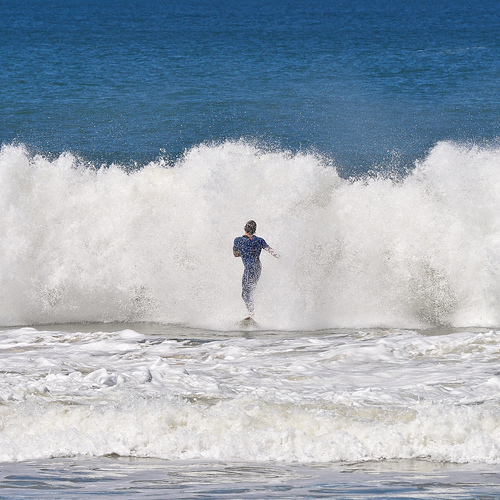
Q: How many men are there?
A: One.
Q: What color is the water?
A: White and blue.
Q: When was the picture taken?
A: Daytime.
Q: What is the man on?
A: The surfboard.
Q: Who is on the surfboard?
A: The man.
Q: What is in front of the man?
A: A wave.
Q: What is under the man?
A: A surfboard.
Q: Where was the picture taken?
A: At the ocean.